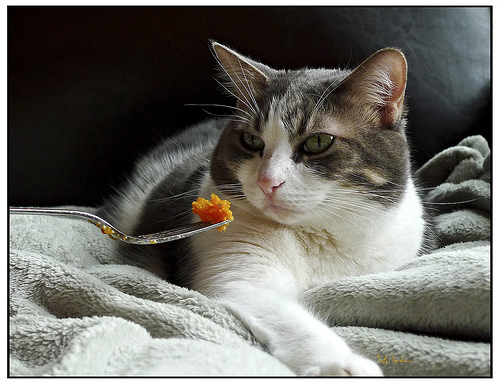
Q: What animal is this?
A: A cat.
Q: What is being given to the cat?
A: Food.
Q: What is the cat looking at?
A: Food.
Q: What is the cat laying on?
A: A blanket.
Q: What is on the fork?
A: Food.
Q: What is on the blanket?
A: A cat.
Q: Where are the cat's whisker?
A: On the cat's face.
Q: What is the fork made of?
A: Silver.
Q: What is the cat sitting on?
A: A sofa.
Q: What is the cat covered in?
A: Fur.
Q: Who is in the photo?
A: No people.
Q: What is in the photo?
A: A cat.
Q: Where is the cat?
A: On a bed.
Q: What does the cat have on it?
A: Whiskers.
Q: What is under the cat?
A: Blanket.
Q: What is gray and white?
A: The cat.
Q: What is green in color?
A: Eyes.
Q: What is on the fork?
A: Food.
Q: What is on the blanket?
A: The cat.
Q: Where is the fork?
A: Near the cat's mouth.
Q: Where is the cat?
A: On a blanket.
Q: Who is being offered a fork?
A: The cat.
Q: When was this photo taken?
A: During the daytime.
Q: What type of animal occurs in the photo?
A: A cat.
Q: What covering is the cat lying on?
A: A blanket.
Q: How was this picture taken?
A: With a camera.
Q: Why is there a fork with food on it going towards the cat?
A: The cat is being offered food.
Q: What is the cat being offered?
A: Food.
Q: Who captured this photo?
A: A photographer.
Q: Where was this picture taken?
A: In a house.